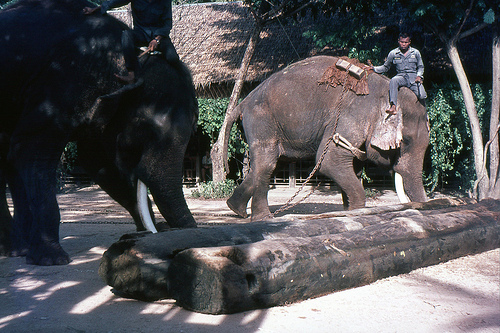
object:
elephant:
[213, 47, 455, 219]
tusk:
[385, 155, 430, 212]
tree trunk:
[434, 30, 491, 200]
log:
[96, 195, 493, 315]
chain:
[264, 70, 356, 218]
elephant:
[2, 0, 196, 267]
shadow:
[1, 205, 269, 330]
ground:
[1, 190, 498, 331]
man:
[369, 25, 437, 117]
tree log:
[166, 199, 498, 316]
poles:
[83, 202, 460, 292]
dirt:
[7, 248, 497, 330]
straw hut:
[180, 2, 252, 80]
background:
[173, 2, 359, 238]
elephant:
[127, 171, 162, 247]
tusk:
[119, 184, 197, 248]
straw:
[207, 34, 220, 61]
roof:
[188, 3, 263, 79]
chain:
[0, 9, 204, 283]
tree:
[445, 67, 496, 168]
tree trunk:
[197, 35, 269, 185]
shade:
[59, 208, 264, 283]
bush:
[425, 80, 481, 184]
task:
[132, 182, 161, 231]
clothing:
[370, 49, 433, 109]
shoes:
[379, 104, 400, 120]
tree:
[204, 20, 254, 192]